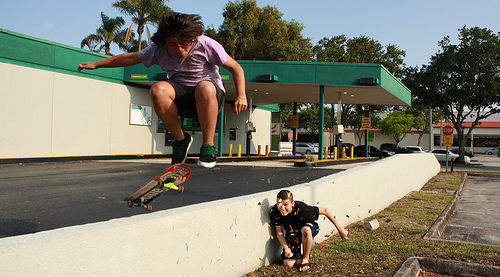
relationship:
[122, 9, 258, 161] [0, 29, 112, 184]
boy near building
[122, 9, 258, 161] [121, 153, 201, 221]
boy on skateboard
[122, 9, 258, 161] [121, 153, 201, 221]
boy in skateboard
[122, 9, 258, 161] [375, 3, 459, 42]
boy near sky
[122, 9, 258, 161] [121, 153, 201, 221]
boy riding skateboard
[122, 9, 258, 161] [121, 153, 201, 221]
boy near skateboard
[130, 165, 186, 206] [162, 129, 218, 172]
skateboard beneath feet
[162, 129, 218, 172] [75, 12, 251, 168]
feet of boy